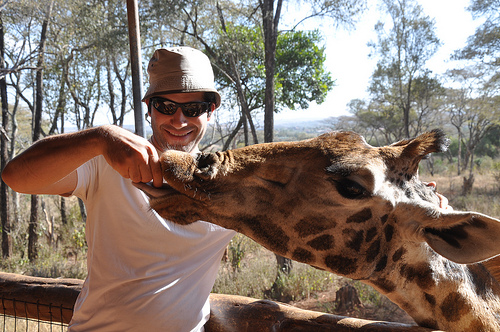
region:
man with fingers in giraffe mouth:
[133, 37, 275, 247]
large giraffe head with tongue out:
[176, 134, 488, 265]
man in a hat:
[132, 40, 234, 156]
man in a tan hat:
[151, 40, 222, 156]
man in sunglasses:
[138, 40, 242, 157]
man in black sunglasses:
[136, 59, 238, 167]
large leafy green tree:
[221, 23, 364, 118]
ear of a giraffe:
[413, 173, 498, 260]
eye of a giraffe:
[306, 139, 385, 214]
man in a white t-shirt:
[65, 44, 268, 319]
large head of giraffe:
[115, 116, 466, 287]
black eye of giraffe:
[327, 158, 372, 208]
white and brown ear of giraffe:
[415, 212, 497, 276]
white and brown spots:
[278, 212, 358, 274]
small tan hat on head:
[144, 35, 222, 93]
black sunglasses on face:
[147, 86, 217, 121]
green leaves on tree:
[232, 16, 324, 91]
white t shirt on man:
[64, 172, 231, 320]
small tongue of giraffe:
[134, 182, 166, 193]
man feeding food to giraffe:
[2, 48, 442, 325]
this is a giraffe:
[106, 96, 498, 319]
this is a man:
[25, 19, 254, 330]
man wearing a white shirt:
[6, 90, 260, 329]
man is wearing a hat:
[108, 33, 236, 113]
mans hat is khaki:
[126, 25, 245, 125]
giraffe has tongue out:
[133, 139, 210, 216]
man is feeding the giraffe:
[12, 34, 316, 330]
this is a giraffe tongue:
[114, 160, 180, 207]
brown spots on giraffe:
[273, 210, 385, 275]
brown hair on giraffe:
[248, 125, 468, 174]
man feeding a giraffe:
[46, 52, 460, 319]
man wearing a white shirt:
[72, 157, 213, 328]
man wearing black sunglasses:
[145, 80, 211, 126]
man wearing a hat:
[135, 30, 251, 121]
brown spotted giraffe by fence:
[165, 122, 485, 318]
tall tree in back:
[366, 17, 471, 158]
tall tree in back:
[453, 6, 498, 110]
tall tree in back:
[196, 10, 301, 165]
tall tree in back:
[60, 15, 150, 127]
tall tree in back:
[20, 10, 97, 170]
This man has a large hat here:
[152, 43, 209, 113]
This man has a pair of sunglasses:
[161, 85, 195, 140]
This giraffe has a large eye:
[336, 160, 382, 249]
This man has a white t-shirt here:
[136, 242, 158, 289]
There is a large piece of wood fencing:
[26, 263, 38, 303]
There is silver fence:
[35, 308, 39, 325]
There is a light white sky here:
[345, 48, 349, 63]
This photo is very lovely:
[149, 69, 335, 326]